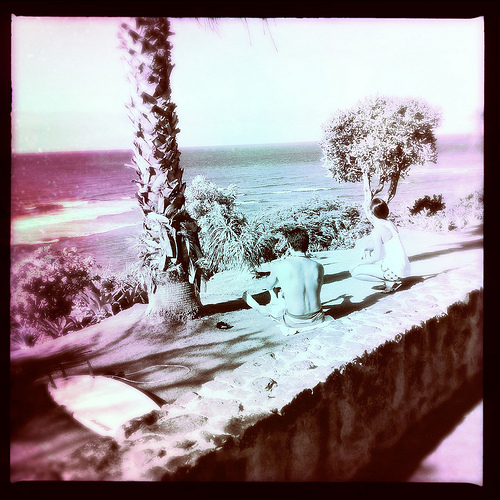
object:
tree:
[97, 13, 236, 331]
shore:
[116, 12, 200, 320]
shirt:
[265, 313, 338, 334]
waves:
[11, 193, 141, 242]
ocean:
[12, 130, 481, 269]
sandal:
[214, 319, 237, 332]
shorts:
[275, 309, 326, 330]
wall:
[11, 261, 484, 481]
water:
[13, 114, 484, 273]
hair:
[286, 227, 311, 252]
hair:
[369, 196, 390, 220]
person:
[236, 221, 331, 330]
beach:
[1, 175, 484, 482]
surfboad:
[41, 355, 166, 445]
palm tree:
[114, 16, 214, 339]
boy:
[240, 226, 322, 331]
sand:
[10, 227, 482, 482]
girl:
[347, 198, 411, 294]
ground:
[8, 226, 483, 480]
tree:
[318, 93, 442, 234]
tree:
[183, 172, 271, 283]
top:
[364, 204, 420, 272]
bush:
[303, 192, 368, 249]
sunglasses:
[321, 301, 340, 311]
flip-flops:
[380, 281, 402, 295]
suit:
[366, 220, 405, 288]